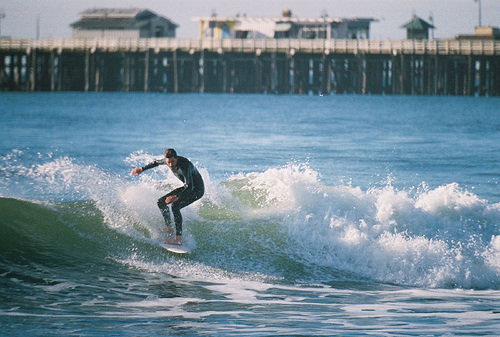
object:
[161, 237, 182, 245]
feet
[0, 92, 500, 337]
water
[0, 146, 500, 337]
wave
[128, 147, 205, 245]
man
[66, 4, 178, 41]
buildings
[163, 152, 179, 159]
glasses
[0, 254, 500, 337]
foam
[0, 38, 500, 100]
pier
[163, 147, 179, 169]
head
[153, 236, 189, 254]
surfboard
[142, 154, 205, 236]
wet suit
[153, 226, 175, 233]
foot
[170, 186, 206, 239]
leg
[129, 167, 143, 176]
hand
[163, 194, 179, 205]
hand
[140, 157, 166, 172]
arm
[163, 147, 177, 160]
hair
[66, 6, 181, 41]
houses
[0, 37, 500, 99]
boardwalk